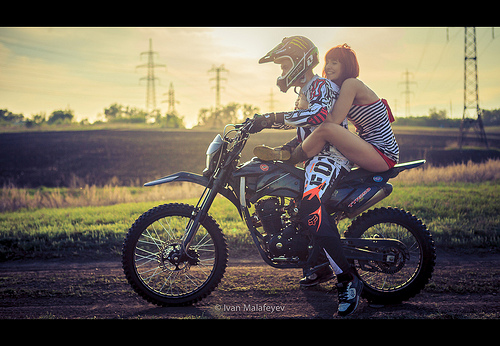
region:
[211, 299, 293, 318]
A watermark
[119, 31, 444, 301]
A couple on a motorbike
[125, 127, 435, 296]
A black motorbike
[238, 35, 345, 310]
A motorbike rider in full protective gear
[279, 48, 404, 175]
A girl with red hair wearing casual summer clothes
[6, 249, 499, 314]
A dirt and gravel road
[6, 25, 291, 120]
Telephone and electric wiring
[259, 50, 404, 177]
A girl on the back of a motorbike, her legs wrapped around the guy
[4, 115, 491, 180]
A large, dark field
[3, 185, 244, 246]
Tall grass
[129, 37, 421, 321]
man and girl on bike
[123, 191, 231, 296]
front tire on bike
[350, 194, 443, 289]
back tire of the bike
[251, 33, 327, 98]
helmet on the biker's head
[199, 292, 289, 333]
person's name written in white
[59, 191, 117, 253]
green grass next to bike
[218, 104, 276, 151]
man's hands on handlebars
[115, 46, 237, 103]
poles above the ground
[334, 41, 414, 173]
girl sitting on bike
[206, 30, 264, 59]
sun shining down on the land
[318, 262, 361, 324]
Person wearing black and white shoes.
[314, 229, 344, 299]
Person wearing black and white pants.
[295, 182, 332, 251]
Orange splashes on knee.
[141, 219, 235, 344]
Black tire on bike.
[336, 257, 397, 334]
Black tire on bike.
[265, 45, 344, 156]
Dark helmet on man's head.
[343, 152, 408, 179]
Woman wearing red shorts.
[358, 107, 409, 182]
Woman wearing striped top.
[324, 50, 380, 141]
Woman has dark hair.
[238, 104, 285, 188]
Person wearing black gloves.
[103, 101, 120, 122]
a tree in a distance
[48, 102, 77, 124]
a tree in a distance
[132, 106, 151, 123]
a tree in a distance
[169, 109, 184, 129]
a tree in a distance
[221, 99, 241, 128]
a tree in a distance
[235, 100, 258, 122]
a tree in a distance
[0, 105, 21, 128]
a tree in a distance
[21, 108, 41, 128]
a tree in a distance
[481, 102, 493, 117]
a tree in a distance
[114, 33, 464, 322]
young couple on a motorcycle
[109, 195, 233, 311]
front motorcycle tire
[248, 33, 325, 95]
man wearing a motorcycle helmet with face shield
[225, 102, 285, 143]
motorcycle handlebars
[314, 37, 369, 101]
young woman with short red hair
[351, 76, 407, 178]
black, white, and red striped halter top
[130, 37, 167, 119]
utility poles and power lines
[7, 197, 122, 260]
green grass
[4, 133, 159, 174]
newly plowed field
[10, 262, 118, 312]
dirt and gravel road